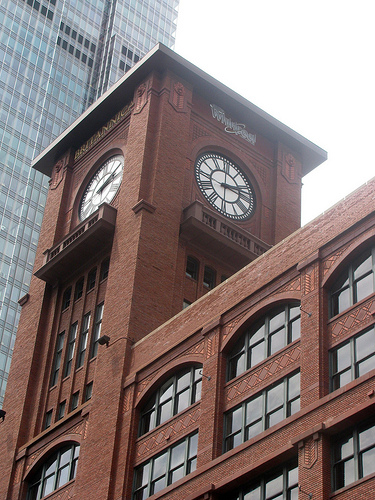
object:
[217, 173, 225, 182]
white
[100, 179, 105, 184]
white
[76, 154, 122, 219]
clock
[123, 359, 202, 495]
window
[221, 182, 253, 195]
hands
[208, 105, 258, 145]
graffiti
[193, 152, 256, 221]
clock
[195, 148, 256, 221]
numbers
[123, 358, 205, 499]
arched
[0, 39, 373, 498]
building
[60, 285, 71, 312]
windows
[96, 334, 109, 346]
camera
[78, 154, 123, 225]
clock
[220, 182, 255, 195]
hand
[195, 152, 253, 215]
roman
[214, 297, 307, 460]
window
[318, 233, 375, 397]
window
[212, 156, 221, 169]
roman numeral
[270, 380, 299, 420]
lines